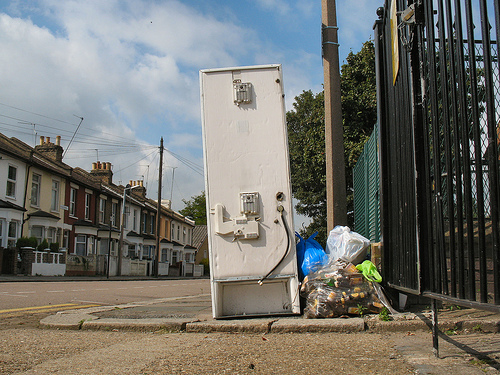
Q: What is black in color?
A: Fence.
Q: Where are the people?
A: No people in photo.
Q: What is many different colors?
A: The homes.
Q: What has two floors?
A: The homes.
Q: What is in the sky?
A: Clouds.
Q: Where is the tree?
A: Behind the pole.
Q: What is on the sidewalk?
A: Trash.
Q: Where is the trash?
A: On the sidewalk.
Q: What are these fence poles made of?
A: Metal.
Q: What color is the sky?
A: Blue and white.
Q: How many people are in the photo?
A: None.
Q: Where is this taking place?
A: In the streets.